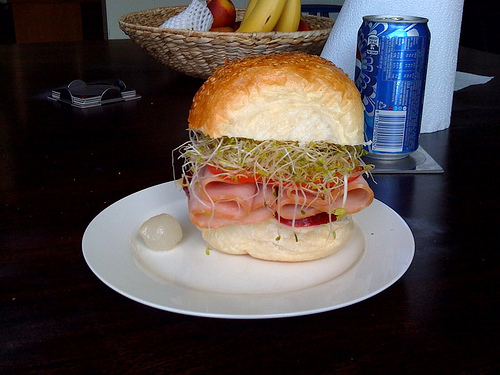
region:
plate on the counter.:
[205, 279, 262, 299]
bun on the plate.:
[252, 233, 284, 254]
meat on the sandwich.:
[226, 190, 243, 208]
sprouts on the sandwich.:
[256, 146, 291, 158]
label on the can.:
[375, 115, 402, 147]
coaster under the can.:
[403, 158, 431, 174]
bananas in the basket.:
[255, 14, 282, 21]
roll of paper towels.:
[435, 31, 446, 123]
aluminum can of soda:
[355, 12, 430, 157]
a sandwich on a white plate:
[84, 50, 414, 321]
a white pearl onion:
[140, 212, 180, 248]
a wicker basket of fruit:
[125, 1, 335, 71]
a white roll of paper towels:
[320, 0, 460, 128]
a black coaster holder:
[50, 78, 137, 105]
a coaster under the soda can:
[362, 144, 445, 172]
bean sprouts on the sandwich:
[176, 134, 367, 185]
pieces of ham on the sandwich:
[189, 173, 371, 229]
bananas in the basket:
[238, 0, 297, 37]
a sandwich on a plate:
[100, 55, 396, 320]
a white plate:
[101, 178, 393, 310]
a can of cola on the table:
[351, 10, 421, 157]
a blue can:
[360, 14, 422, 157]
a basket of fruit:
[133, 8, 310, 58]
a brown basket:
[129, 13, 325, 75]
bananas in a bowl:
[234, 5, 311, 43]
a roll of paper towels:
[331, 4, 462, 127]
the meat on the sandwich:
[196, 175, 362, 219]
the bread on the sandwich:
[183, 50, 367, 142]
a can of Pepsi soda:
[342, 4, 448, 176]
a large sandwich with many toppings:
[172, 43, 381, 272]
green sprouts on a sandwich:
[180, 126, 374, 202]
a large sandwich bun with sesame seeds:
[183, 50, 370, 153]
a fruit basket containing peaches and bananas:
[123, 0, 336, 77]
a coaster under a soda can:
[349, 128, 465, 181]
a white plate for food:
[77, 163, 428, 331]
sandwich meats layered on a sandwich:
[178, 161, 379, 240]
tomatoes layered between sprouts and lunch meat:
[197, 158, 367, 192]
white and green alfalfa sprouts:
[171, 130, 366, 177]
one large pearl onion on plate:
[134, 214, 186, 251]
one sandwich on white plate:
[66, 45, 410, 325]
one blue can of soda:
[351, 9, 437, 165]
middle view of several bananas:
[236, 3, 308, 32]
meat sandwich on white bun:
[185, 52, 377, 262]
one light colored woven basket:
[113, 10, 325, 73]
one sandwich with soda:
[149, 15, 436, 264]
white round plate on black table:
[75, 260, 417, 352]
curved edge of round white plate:
[74, 220, 129, 290]